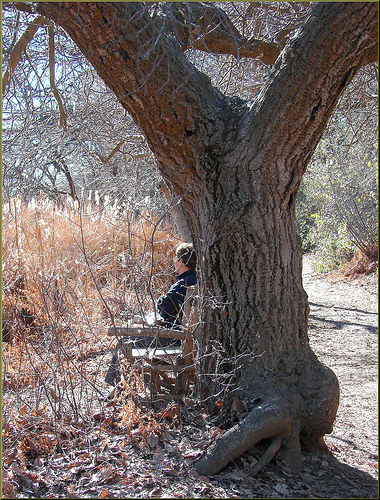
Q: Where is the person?
A: By the tree.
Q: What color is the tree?
A: Brown.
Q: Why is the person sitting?
A: Tired.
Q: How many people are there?
A: One.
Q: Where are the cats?
A: Nowhere.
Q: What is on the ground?
A: Leaves.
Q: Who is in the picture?
A: A man.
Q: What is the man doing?
A: Sitting.